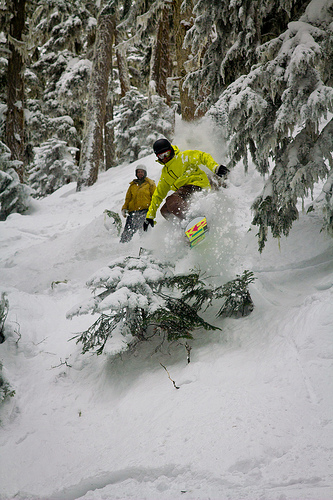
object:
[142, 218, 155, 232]
glove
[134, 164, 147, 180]
hat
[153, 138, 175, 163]
hat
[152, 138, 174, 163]
head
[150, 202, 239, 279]
snow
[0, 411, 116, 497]
snow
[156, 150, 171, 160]
goggles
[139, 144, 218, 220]
jacket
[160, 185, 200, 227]
pants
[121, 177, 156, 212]
man's jacket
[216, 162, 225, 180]
gloves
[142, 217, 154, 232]
hand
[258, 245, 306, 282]
snow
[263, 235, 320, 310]
ground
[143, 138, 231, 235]
man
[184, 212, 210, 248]
snowboarder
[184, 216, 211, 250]
air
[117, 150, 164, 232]
man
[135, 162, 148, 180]
head